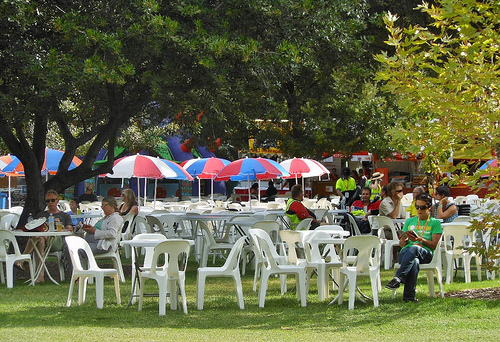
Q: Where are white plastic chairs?
A: On the lawn.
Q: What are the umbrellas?
A: Raised.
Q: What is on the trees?
A: Leaves.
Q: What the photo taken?
A: During the daytime.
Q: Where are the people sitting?
A: Shade of tree.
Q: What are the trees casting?
A: Shadow.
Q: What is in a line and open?
A: Umbrellas.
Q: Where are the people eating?
A: In the park.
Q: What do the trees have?
A: Leaves.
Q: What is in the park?
A: Chairs.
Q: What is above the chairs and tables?
A: Umbrellas.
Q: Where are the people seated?
A: On chairs.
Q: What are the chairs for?
A: Sitting.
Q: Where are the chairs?
A: On the grass.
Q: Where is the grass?
A: On the ground.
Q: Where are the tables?
A: Next to the chairs.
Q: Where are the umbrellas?
A: In the tables.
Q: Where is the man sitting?
A: IN a lawn chair.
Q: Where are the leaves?
A: On the trees.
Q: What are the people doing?
A: Sitting.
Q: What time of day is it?
A: Afternoon.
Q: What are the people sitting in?
A: Chairs.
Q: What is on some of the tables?
A: Umbrellas.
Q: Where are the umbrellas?
A: On some of the tables.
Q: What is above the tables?
A: Trees.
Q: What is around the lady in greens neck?
A: Lanyard.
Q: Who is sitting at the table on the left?
A: A man and a woman.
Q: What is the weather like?
A: Sunny.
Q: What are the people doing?
A: Sitting.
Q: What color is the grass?
A: Green.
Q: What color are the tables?
A: White.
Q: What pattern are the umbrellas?
A: Striped.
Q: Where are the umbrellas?
A: Above tables.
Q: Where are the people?
A: In chairs.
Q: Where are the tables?
A: In grass.